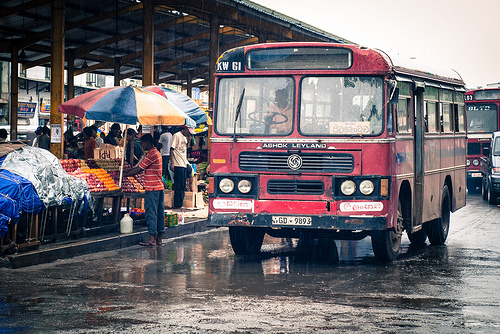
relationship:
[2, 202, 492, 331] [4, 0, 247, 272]
water in market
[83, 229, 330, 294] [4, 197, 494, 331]
water on road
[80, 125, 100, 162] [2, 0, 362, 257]
person in marketplace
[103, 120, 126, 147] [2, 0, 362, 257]
person in marketplace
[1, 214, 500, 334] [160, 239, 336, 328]
road has water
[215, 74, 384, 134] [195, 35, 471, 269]
windshield of bus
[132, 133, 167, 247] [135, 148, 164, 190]
man wearing shirt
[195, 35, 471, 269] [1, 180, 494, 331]
bus on road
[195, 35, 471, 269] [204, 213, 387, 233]
bus has black bumper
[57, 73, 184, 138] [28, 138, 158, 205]
umbrellas over fruit stand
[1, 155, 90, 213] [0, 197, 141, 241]
tarps covering table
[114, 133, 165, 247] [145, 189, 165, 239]
man wearing pants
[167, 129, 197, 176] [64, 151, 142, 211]
man has fruit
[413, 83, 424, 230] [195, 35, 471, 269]
door on bus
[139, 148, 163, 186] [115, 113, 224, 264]
shirt on man